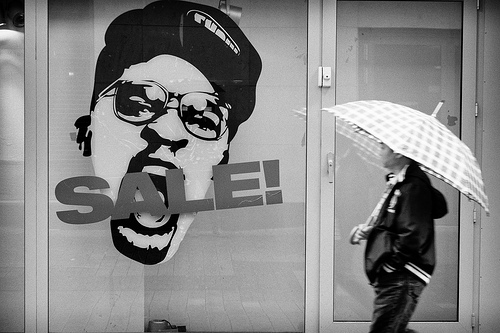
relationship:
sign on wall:
[56, 0, 284, 268] [1, 2, 321, 333]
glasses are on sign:
[92, 81, 231, 141] [56, 0, 284, 268]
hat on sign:
[91, 0, 263, 142] [56, 0, 284, 268]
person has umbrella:
[350, 141, 450, 333] [321, 99, 490, 245]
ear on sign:
[74, 116, 92, 157] [56, 0, 284, 268]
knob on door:
[326, 152, 335, 184] [324, 1, 475, 333]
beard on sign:
[110, 218, 176, 265] [56, 0, 284, 268]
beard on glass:
[110, 218, 176, 265] [1, 2, 321, 333]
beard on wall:
[110, 218, 176, 265] [1, 2, 321, 333]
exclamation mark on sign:
[263, 160, 285, 208] [56, 0, 284, 268]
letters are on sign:
[57, 161, 264, 226] [56, 0, 284, 268]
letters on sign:
[57, 161, 264, 226] [56, 0, 284, 268]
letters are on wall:
[57, 161, 264, 226] [1, 2, 321, 333]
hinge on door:
[477, 0, 480, 7] [324, 1, 475, 333]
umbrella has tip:
[321, 99, 490, 245] [431, 98, 446, 120]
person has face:
[350, 141, 450, 333] [380, 144, 390, 169]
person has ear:
[350, 141, 450, 333] [395, 153, 401, 159]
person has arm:
[350, 141, 450, 333] [383, 182, 431, 271]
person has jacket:
[350, 141, 450, 333] [365, 164, 447, 286]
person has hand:
[350, 141, 450, 333] [355, 225, 374, 243]